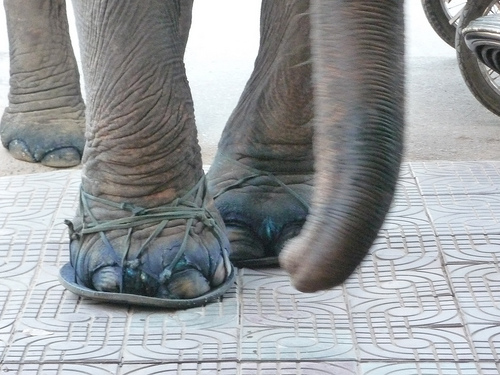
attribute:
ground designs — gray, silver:
[20, 315, 499, 370]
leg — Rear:
[68, 1, 237, 311]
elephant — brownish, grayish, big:
[1, 4, 423, 314]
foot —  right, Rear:
[50, 78, 242, 328]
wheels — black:
[403, 15, 495, 92]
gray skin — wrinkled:
[72, 0, 204, 207]